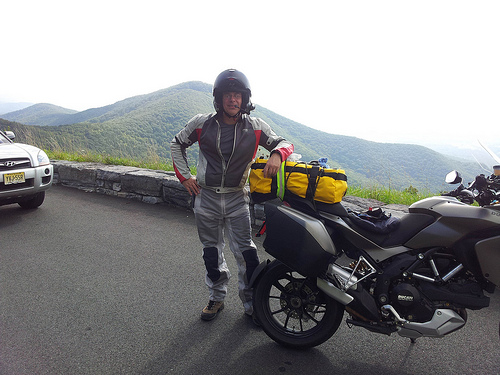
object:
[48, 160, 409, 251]
brick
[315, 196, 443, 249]
seat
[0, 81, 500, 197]
hill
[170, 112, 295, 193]
jacket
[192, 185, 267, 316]
silver pants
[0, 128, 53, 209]
car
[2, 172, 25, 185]
plate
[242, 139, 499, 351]
vehicle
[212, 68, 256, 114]
helmet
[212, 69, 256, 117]
head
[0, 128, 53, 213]
suv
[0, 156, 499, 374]
road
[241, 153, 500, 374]
bike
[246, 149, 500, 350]
motorcycle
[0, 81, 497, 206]
mountains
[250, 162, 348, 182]
strap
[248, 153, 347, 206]
bag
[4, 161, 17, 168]
logo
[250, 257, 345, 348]
wheel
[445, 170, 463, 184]
mirror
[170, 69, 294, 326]
man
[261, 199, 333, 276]
tank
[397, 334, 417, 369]
kickstand